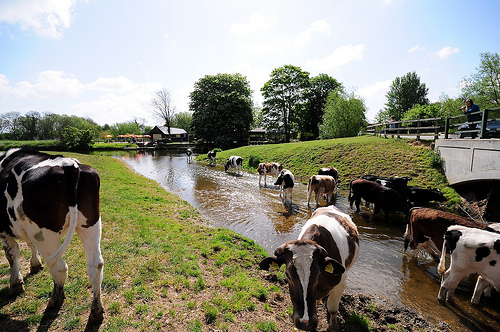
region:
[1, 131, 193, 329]
a cow near a river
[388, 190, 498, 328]
cows in the river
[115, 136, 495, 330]
many cows in the river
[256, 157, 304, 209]
cow in the water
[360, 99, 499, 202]
a bridge with a fence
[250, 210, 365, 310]
brown and white cow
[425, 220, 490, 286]
brown and white cow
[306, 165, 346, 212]
brown and white cow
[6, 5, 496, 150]
blue sky and white clouds over rural area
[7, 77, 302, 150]
brown houses nestled between trees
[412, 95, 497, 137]
man with black camera standing on overpass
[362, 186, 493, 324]
cows standing in shallow and clear water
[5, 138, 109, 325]
black rump of cow with white legs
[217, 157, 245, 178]
cow bending neck to drink water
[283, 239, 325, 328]
cow with white stripe down center of face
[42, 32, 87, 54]
white clouds in blue sky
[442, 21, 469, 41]
white clouds in blue sky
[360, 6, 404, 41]
white clouds in blue sky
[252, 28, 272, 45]
white clouds in blue sky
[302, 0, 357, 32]
white clouds in blue sky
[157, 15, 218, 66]
white clouds in blue sky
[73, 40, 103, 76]
white clouds in blue sky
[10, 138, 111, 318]
cow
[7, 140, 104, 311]
cow near a lake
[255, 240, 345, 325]
face of a cow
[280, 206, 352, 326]
cow near a lake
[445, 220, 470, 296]
cow near a lake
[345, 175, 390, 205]
brown cow in water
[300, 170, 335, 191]
brown cow in water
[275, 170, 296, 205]
black and white cow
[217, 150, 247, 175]
cow standing in water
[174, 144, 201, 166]
cow standing in water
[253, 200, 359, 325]
cow standing near water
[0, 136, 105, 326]
cow standing near water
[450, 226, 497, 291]
cow standing in water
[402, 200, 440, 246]
cow standing in water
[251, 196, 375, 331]
the cow is white and brown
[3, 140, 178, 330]
The cow is standing on grass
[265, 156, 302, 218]
The cow is standing in the water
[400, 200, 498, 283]
The cow is brown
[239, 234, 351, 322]
The cow has ears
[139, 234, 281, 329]
The grass has dead patches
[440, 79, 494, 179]
A man is standing on the bridge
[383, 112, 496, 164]
The bridge railing is made of wood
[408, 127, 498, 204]
The bridge is concrete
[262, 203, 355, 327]
the cow is facing the photographer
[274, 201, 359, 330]
the cow is brown and white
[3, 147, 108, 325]
the cow is standing still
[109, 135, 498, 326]
a river is running across the field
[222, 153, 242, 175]
the cow is drinking water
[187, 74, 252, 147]
a tree is in the background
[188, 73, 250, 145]
the tree is full of leaves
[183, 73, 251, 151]
the leaves are green in color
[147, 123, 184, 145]
a barn is on the background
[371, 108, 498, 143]
a fence is above the field